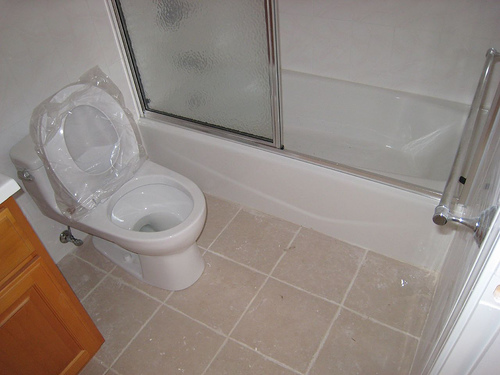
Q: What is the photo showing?
A: It is showing a bathroom.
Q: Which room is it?
A: It is a bathroom.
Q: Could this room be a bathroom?
A: Yes, it is a bathroom.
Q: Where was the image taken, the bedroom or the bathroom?
A: It was taken at the bathroom.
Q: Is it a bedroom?
A: No, it is a bathroom.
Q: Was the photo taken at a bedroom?
A: No, the picture was taken in a bathroom.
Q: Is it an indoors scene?
A: Yes, it is indoors.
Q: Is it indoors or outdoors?
A: It is indoors.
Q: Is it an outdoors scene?
A: No, it is indoors.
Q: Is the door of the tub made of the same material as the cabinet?
A: No, the door is made of glass and the cabinet is made of wood.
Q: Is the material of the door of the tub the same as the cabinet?
A: No, the door is made of glass and the cabinet is made of wood.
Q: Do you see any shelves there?
A: No, there are no shelves.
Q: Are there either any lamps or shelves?
A: No, there are no shelves or lamps.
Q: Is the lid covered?
A: Yes, the lid is covered.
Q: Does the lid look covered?
A: Yes, the lid is covered.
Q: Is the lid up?
A: Yes, the lid is up.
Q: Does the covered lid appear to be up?
A: Yes, the lid is up.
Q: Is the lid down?
A: No, the lid is up.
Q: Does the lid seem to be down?
A: No, the lid is up.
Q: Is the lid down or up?
A: The lid is up.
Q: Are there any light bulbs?
A: No, there are no light bulbs.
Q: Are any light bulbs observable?
A: No, there are no light bulbs.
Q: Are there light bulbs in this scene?
A: No, there are no light bulbs.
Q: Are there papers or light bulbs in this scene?
A: No, there are no light bulbs or papers.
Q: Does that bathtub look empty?
A: Yes, the bathtub is empty.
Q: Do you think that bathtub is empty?
A: Yes, the bathtub is empty.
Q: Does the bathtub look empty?
A: Yes, the bathtub is empty.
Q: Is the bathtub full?
A: No, the bathtub is empty.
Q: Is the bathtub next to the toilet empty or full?
A: The bathtub is empty.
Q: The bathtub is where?
A: The bathtub is in the bathroom.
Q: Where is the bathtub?
A: The bathtub is in the bathroom.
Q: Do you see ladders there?
A: No, there are no ladders.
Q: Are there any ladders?
A: No, there are no ladders.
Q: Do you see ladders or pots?
A: No, there are no ladders or pots.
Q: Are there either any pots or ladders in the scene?
A: No, there are no ladders or pots.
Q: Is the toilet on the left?
A: Yes, the toilet is on the left of the image.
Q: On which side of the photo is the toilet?
A: The toilet is on the left of the image.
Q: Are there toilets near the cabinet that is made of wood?
A: Yes, there is a toilet near the cabinet.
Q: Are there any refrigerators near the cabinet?
A: No, there is a toilet near the cabinet.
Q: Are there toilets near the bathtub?
A: Yes, there is a toilet near the bathtub.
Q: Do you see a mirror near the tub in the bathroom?
A: No, there is a toilet near the bathtub.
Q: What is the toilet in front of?
A: The toilet is in front of the wall.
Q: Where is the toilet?
A: The toilet is in the bathroom.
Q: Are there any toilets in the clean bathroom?
A: Yes, there is a toilet in the bathroom.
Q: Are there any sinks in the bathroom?
A: No, there is a toilet in the bathroom.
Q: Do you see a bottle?
A: No, there are no bottles.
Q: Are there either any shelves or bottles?
A: No, there are no bottles or shelves.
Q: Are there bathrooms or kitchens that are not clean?
A: No, there is a bathroom but it is clean.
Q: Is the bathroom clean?
A: Yes, the bathroom is clean.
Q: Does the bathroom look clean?
A: Yes, the bathroom is clean.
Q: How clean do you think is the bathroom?
A: The bathroom is clean.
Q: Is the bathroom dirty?
A: No, the bathroom is clean.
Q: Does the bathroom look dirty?
A: No, the bathroom is clean.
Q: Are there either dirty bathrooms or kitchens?
A: No, there is a bathroom but it is clean.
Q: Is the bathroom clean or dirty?
A: The bathroom is clean.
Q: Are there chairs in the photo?
A: No, there are no chairs.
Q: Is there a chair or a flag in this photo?
A: No, there are no chairs or flags.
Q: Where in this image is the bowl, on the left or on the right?
A: The bowl is on the left of the image.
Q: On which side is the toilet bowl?
A: The bowl is on the left of the image.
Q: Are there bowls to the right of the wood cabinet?
A: Yes, there is a bowl to the right of the cabinet.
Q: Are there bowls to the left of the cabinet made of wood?
A: No, the bowl is to the right of the cabinet.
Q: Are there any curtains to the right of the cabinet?
A: No, there is a bowl to the right of the cabinet.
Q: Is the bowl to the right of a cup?
A: No, the bowl is to the right of a cabinet.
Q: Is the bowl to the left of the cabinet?
A: No, the bowl is to the right of the cabinet.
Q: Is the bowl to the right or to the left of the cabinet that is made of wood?
A: The bowl is to the right of the cabinet.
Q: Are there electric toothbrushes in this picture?
A: No, there are no electric toothbrushes.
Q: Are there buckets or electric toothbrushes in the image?
A: No, there are no electric toothbrushes or buckets.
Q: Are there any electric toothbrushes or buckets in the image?
A: No, there are no electric toothbrushes or buckets.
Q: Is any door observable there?
A: Yes, there is a door.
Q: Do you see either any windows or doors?
A: Yes, there is a door.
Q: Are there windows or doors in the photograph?
A: Yes, there is a door.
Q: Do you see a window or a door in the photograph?
A: Yes, there is a door.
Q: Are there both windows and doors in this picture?
A: No, there is a door but no windows.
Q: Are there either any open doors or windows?
A: Yes, there is an open door.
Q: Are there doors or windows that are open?
A: Yes, the door is open.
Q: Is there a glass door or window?
A: Yes, there is a glass door.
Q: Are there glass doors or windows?
A: Yes, there is a glass door.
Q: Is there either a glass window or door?
A: Yes, there is a glass door.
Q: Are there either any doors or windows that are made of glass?
A: Yes, the door is made of glass.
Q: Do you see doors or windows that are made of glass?
A: Yes, the door is made of glass.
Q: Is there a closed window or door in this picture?
A: Yes, there is a closed door.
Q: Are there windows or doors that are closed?
A: Yes, the door is closed.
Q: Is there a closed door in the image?
A: Yes, there is a closed door.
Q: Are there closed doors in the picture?
A: Yes, there is a closed door.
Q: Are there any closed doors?
A: Yes, there is a closed door.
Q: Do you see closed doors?
A: Yes, there is a closed door.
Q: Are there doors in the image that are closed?
A: Yes, there is a door that is closed.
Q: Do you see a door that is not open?
A: Yes, there is an closed door.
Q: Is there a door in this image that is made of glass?
A: Yes, there is a door that is made of glass.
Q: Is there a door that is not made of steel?
A: Yes, there is a door that is made of glass.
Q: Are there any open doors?
A: Yes, there is an open door.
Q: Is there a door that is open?
A: Yes, there is a door that is open.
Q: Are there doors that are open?
A: Yes, there is a door that is open.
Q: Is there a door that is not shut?
A: Yes, there is a open door.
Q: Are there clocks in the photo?
A: No, there are no clocks.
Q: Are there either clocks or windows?
A: No, there are no clocks or windows.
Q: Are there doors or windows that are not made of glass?
A: No, there is a door but it is made of glass.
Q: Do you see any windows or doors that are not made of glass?
A: No, there is a door but it is made of glass.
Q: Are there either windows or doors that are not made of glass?
A: No, there is a door but it is made of glass.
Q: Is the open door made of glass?
A: Yes, the door is made of glass.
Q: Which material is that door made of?
A: The door is made of glass.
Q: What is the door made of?
A: The door is made of glass.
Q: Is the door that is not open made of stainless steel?
A: No, the door is made of glass.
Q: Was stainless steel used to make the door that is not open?
A: No, the door is made of glass.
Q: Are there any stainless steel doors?
A: No, there is a door but it is made of glass.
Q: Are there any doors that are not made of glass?
A: No, there is a door but it is made of glass.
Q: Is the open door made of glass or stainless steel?
A: The door is made of glass.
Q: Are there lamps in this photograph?
A: No, there are no lamps.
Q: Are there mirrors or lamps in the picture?
A: No, there are no lamps or mirrors.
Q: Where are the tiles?
A: The tiles are on the floor.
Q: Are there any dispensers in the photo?
A: No, there are no dispensers.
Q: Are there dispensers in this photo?
A: No, there are no dispensers.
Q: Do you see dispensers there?
A: No, there are no dispensers.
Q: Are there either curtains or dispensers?
A: No, there are no dispensers or curtains.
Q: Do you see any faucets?
A: No, there are no faucets.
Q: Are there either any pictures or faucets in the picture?
A: No, there are no faucets or pictures.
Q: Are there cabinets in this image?
A: Yes, there is a cabinet.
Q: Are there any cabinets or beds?
A: Yes, there is a cabinet.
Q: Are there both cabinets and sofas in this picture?
A: No, there is a cabinet but no sofas.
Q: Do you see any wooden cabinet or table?
A: Yes, there is a wood cabinet.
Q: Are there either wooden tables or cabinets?
A: Yes, there is a wood cabinet.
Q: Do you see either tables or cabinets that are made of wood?
A: Yes, the cabinet is made of wood.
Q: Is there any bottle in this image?
A: No, there are no bottles.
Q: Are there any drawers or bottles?
A: No, there are no bottles or drawers.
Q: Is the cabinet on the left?
A: Yes, the cabinet is on the left of the image.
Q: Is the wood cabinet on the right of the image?
A: No, the cabinet is on the left of the image.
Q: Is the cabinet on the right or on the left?
A: The cabinet is on the left of the image.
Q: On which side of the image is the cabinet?
A: The cabinet is on the left of the image.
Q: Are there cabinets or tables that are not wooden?
A: No, there is a cabinet but it is wooden.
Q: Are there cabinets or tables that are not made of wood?
A: No, there is a cabinet but it is made of wood.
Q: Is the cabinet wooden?
A: Yes, the cabinet is wooden.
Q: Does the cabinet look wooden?
A: Yes, the cabinet is wooden.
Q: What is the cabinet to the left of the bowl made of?
A: The cabinet is made of wood.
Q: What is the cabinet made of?
A: The cabinet is made of wood.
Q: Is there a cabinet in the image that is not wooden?
A: No, there is a cabinet but it is wooden.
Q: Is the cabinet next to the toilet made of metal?
A: No, the cabinet is made of wood.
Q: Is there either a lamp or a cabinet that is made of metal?
A: No, there is a cabinet but it is made of wood.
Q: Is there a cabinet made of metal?
A: No, there is a cabinet but it is made of wood.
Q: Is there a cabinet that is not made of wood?
A: No, there is a cabinet but it is made of wood.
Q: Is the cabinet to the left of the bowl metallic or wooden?
A: The cabinet is wooden.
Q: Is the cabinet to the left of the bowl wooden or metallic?
A: The cabinet is wooden.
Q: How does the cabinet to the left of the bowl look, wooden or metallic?
A: The cabinet is wooden.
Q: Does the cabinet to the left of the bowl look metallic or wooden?
A: The cabinet is wooden.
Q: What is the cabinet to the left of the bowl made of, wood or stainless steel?
A: The cabinet is made of wood.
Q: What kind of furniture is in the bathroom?
A: The piece of furniture is a cabinet.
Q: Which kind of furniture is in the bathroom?
A: The piece of furniture is a cabinet.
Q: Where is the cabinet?
A: The cabinet is in the bathroom.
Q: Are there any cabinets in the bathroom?
A: Yes, there is a cabinet in the bathroom.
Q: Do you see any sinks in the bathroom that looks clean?
A: No, there is a cabinet in the bathroom.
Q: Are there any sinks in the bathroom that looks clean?
A: No, there is a cabinet in the bathroom.